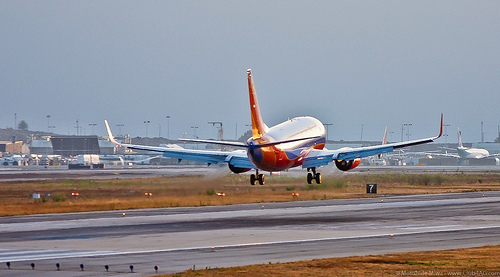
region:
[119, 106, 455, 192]
white plane is landing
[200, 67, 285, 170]
white plane has red tail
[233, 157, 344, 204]
small wheels on plane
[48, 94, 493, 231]
plane lands on runway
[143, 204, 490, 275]
runway is dark grey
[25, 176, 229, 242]
dark brown field under plane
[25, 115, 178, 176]
airport buildings in distance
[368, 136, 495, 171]
other planes to right of plane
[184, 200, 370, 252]
plane casts shadow on ground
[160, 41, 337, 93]
sky is grey and hazy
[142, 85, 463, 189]
the plane is in the air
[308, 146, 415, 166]
the wing is blue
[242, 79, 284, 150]
the tail is orange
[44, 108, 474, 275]
the scene is in an airport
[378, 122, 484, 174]
the planes are parked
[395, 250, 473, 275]
the grass is brown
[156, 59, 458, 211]
the plane is taking off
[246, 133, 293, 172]
the plane part is orange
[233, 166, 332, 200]
the wheels are four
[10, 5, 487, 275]
the scene is outdoors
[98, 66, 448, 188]
Plane just above the ground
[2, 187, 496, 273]
Length of smooth runway tarmac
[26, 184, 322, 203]
Line of lit runway light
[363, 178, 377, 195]
Number inscription of a black surface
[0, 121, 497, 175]
Busy area of an airport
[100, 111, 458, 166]
Wingspan of an aircraft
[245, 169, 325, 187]
Rear landing gear of an aircraft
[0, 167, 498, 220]
Sparse vegetation between runways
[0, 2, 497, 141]
Clear blue sky expanse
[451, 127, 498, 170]
Plane parked on the tarmac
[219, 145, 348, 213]
airplane taking off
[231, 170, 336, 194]
wheels on the plane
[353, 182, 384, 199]
7 on a sign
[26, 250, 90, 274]
lights on the runway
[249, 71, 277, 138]
tail of the plane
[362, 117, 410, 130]
lights are the airport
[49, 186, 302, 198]
lights in the grass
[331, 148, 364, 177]
engine on the plane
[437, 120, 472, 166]
airplane at the airport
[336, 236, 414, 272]
grass on the side of the runway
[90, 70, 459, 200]
plane taking off of a runway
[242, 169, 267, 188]
landing gear on a plane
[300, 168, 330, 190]
landing gear on a plane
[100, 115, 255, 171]
wing of a plane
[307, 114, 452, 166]
wing of a plane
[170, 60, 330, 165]
tail section of a plane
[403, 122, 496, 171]
plane parked at an airport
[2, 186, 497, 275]
runway at an airport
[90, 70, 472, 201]
red and white airplane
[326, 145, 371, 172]
engine on a plane